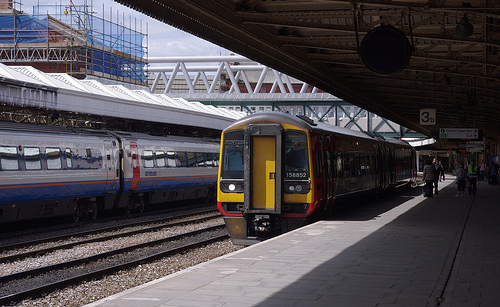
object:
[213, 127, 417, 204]
train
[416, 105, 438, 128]
sign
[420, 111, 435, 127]
3b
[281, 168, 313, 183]
number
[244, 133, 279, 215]
door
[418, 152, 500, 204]
people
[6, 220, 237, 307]
gravel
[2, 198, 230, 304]
tracks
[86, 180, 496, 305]
platform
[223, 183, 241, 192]
headlights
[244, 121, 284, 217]
frame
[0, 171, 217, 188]
strip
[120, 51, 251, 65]
pipe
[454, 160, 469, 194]
person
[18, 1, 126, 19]
cloud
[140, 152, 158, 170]
window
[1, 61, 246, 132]
roof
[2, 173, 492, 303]
ground